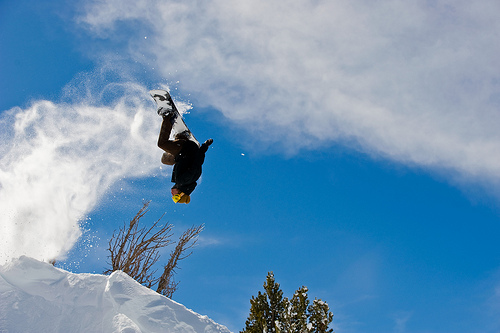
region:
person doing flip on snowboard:
[87, 16, 269, 236]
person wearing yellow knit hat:
[151, 169, 198, 219]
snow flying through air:
[8, 74, 196, 268]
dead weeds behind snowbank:
[99, 191, 206, 309]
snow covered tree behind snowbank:
[234, 266, 340, 324]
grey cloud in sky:
[96, 7, 489, 196]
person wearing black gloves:
[194, 128, 243, 165]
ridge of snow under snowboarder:
[5, 246, 225, 330]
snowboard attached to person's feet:
[140, 78, 204, 160]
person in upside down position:
[137, 71, 228, 223]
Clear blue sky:
[245, 207, 408, 298]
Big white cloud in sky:
[241, 82, 435, 233]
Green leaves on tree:
[238, 277, 327, 327]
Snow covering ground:
[24, 260, 139, 331]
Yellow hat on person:
[156, 177, 201, 229]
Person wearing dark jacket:
[163, 155, 223, 185]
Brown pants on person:
[128, 125, 188, 168]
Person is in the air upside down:
[152, 84, 212, 182]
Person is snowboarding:
[129, 85, 259, 268]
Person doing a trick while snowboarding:
[126, 116, 225, 233]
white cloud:
[96, 46, 496, 144]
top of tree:
[232, 244, 328, 331]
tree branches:
[72, 183, 199, 290]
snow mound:
[10, 250, 173, 331]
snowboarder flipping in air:
[142, 78, 231, 219]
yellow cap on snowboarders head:
[158, 192, 224, 218]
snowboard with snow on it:
[143, 76, 205, 150]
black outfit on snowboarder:
[159, 116, 214, 198]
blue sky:
[248, 175, 428, 270]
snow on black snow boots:
[148, 105, 177, 119]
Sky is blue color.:
[233, 172, 460, 258]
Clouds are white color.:
[240, 36, 435, 82]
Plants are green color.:
[245, 296, 330, 327]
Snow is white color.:
[15, 287, 87, 307]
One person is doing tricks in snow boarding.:
[125, 85, 230, 200]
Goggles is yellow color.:
[162, 181, 189, 206]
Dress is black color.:
[147, 130, 207, 175]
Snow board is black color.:
[145, 91, 205, 151]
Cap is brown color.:
[171, 193, 201, 207]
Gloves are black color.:
[191, 134, 221, 155]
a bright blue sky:
[0, 0, 499, 331]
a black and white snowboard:
[145, 87, 200, 147]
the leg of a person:
[154, 117, 191, 157]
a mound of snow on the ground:
[0, 254, 235, 331]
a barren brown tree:
[99, 195, 210, 302]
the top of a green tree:
[240, 266, 335, 331]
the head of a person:
[165, 183, 195, 205]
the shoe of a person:
[153, 107, 180, 119]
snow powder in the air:
[0, 80, 193, 272]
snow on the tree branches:
[269, 282, 335, 331]